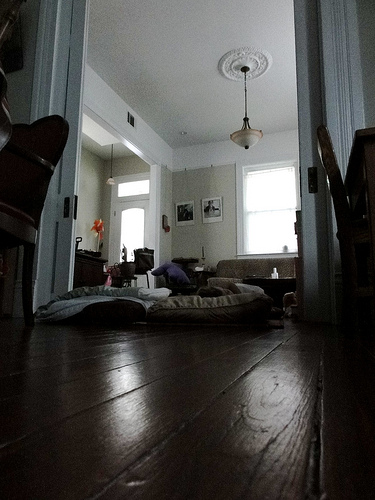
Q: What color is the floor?
A: Brown.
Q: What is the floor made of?
A: Wood.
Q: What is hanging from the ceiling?
A: A light.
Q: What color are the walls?
A: White.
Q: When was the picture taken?
A: Daytime.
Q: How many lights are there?
A: One.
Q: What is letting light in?
A: Windows.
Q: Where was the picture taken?
A: In the living room.